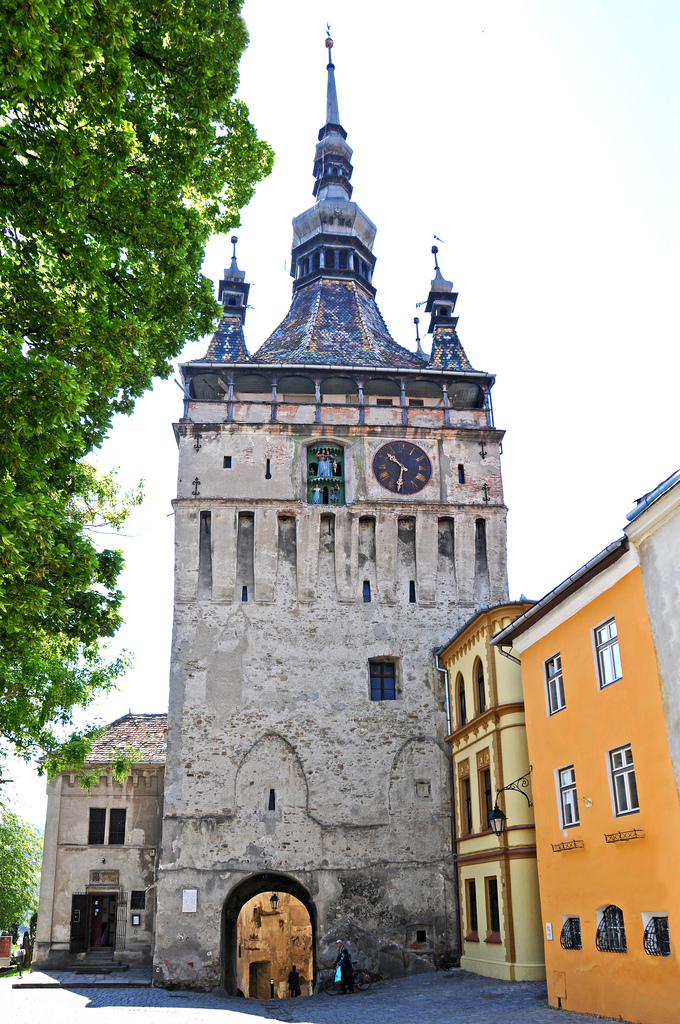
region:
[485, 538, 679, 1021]
building has orange paint on it's side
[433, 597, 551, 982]
building is beige and tan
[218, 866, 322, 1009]
doorway is arched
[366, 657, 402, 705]
window has glass panes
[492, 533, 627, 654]
gutter is on rooftop edge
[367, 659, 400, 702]
window has six panes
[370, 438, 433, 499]
clock is round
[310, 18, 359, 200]
spire sits on top of a building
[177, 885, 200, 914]
rectangle is white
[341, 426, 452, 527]
this is a clock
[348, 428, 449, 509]
the clock is black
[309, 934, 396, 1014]
person next to a bike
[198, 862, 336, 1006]
arch on the building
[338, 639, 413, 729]
window on the tower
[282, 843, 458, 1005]
discolor on the tower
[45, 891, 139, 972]
door to the building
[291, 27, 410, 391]
steeple on the tower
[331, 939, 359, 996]
human carries bag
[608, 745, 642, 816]
window has four panes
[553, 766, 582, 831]
window has four panes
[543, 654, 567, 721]
window has four panes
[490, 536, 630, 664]
gutter is on edge of roof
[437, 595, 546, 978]
building is tan and beige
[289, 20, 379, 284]
steeple is on top of building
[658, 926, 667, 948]
window on the building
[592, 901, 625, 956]
window on the building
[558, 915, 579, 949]
window on the building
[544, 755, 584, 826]
window on the building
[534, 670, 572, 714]
window on the building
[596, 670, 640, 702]
window on the building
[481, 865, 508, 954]
window on the building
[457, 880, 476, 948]
window on the building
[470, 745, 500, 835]
window on the building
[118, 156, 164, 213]
green leaves on the tree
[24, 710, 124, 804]
green leaves on the tree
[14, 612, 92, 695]
green leaves on the tree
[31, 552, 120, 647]
green leaves on the tree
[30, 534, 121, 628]
green leaves on the tree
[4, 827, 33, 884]
green leaves on the tree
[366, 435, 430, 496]
black clock on the building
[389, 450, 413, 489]
hands on the black clock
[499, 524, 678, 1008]
yellow building on the right side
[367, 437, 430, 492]
roman numerals on the clock face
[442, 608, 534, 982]
light yellow building with brown trim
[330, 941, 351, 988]
person carrying green bag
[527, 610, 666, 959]
windows in the yellow building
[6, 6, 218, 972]
tall green tree beside the buildings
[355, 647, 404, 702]
window below the clock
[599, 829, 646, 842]
wire flowerpot holder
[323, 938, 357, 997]
man holding a blue bag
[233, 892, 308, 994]
lit archway in building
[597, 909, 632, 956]
black metal bars over window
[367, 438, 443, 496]
black and gold clock built into building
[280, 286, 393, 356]
colorful tiles in steeple base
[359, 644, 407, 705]
small dark window in building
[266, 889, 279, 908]
lantern hanging from archway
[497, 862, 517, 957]
brown brick trim on building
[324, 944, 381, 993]
man walking with bicycle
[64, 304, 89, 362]
green leaves on the tree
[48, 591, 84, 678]
green leaves on the tree